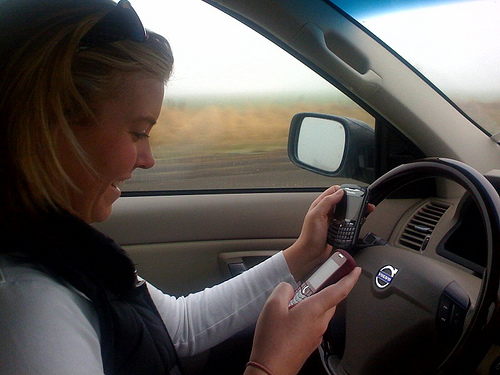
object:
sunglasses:
[76, 0, 150, 51]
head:
[1, 0, 173, 225]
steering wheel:
[310, 156, 500, 374]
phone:
[286, 247, 358, 313]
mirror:
[287, 112, 348, 175]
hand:
[251, 266, 363, 373]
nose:
[134, 137, 156, 171]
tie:
[247, 361, 274, 374]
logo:
[372, 264, 398, 290]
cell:
[326, 181, 369, 250]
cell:
[285, 250, 357, 312]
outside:
[114, 1, 500, 191]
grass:
[143, 95, 376, 153]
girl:
[1, 0, 374, 374]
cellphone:
[326, 185, 365, 250]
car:
[0, 0, 500, 373]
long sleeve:
[136, 249, 300, 358]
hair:
[0, 0, 174, 213]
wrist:
[239, 361, 276, 373]